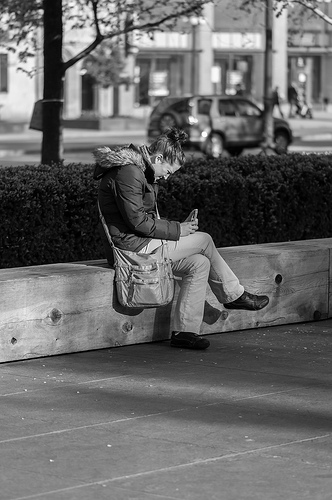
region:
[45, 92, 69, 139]
part fo a line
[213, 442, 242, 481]
part pof a line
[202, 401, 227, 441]
part fo a floor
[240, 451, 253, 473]
part of a floor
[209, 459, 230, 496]
part fo a floor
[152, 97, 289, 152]
A car in the photo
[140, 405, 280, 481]
A road with tarmac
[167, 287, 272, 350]
Shoes in the photo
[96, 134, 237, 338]
A woman seated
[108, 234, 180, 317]
A handbag in the photo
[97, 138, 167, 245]
A jacket in the photo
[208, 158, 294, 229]
A hedge in the photo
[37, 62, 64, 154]
A tree trunk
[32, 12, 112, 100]
A tree in the photo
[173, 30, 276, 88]
A building in the photo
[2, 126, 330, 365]
Lady sitting on wooden plank.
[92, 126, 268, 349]
Lady with black short hooded coat.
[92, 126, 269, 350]
Lady with satchel bag purse.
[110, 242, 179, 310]
Satchel bag purse with front pocket.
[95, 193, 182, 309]
Satchel bag purse with strap.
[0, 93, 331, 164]
Truck driving down street.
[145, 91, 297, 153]
Truck with side window.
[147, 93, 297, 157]
Truck with back window.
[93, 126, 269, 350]
Lady with black shoes.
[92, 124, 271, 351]
Lady looking at cell phone.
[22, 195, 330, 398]
this is a woman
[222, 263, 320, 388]
this is a shoe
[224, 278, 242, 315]
the shoe is black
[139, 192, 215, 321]
these are some pants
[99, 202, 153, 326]
this is a bag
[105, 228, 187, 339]
the bag has a strap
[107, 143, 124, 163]
this is a fur capped coat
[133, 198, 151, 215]
this is a jacket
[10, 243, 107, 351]
this is a bench